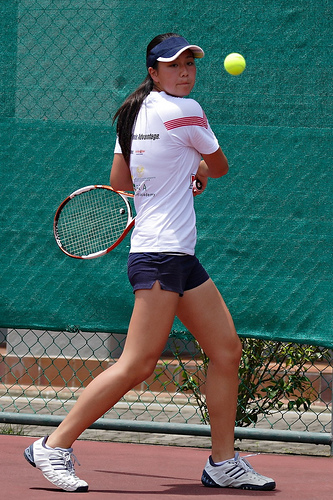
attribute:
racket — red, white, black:
[52, 183, 138, 261]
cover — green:
[0, 1, 332, 348]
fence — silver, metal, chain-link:
[2, 4, 331, 444]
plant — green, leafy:
[161, 331, 323, 449]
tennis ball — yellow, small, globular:
[224, 52, 246, 77]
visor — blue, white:
[147, 37, 205, 63]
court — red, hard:
[2, 435, 332, 499]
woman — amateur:
[24, 33, 276, 491]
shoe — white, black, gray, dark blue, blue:
[23, 435, 89, 493]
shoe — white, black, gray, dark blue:
[199, 454, 276, 492]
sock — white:
[43, 443, 53, 451]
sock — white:
[216, 458, 234, 467]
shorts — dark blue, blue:
[127, 252, 211, 297]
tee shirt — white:
[113, 91, 221, 255]